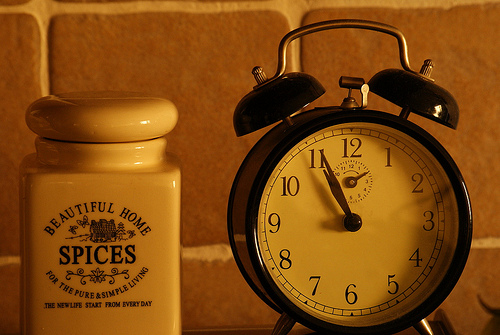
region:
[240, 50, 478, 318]
alarm clock kept in the table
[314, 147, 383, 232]
two needles in the clock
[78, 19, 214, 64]
brown color wall tiles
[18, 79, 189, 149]
top of the jar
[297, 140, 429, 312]
white color background of the clock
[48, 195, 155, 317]
text written in the jar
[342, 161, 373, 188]
alarm needle in the clcok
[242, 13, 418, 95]
handle of the clock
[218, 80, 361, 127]
black color alarm clock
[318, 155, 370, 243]
black color needles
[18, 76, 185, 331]
This is a jar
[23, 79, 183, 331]
The jar is made of glass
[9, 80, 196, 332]
The jar contains beautiful home spices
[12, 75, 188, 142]
The cap is round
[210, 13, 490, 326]
This is a clock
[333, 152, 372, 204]
There is a small clock within the big clock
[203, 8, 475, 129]
An alarm on the top of the clock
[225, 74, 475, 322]
The time is 10:55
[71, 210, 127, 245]
There is a small home on the jar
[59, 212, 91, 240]
Two butterflies flying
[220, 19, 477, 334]
clock sitting on table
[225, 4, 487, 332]
clock itself is round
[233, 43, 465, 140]
alarm bells on top of clock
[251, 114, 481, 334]
time shows 10:55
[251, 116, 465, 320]
regular numbers on clock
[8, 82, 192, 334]
container on the table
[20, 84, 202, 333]
container holds the spices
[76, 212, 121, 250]
picture of building on container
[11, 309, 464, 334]
table holding the items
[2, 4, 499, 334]
back wall is tile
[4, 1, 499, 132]
The wall is brick.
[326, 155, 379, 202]
Smaller clock on the clock.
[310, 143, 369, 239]
The clock hands are black.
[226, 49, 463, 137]
Bells on the clock.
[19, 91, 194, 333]
Spice jar next to the clock.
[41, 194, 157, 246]
Beautiful Home on the jar.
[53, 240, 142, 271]
Spices on the jar.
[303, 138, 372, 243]
The clock hands are both are "11".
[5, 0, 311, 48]
The grout is white.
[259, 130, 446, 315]
The numbers are black.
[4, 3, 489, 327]
a clock and some spices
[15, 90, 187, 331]
ceramic bottle of spices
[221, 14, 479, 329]
a vintage alarm clock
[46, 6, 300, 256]
ceramic square tile on wall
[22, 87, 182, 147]
lid of spice container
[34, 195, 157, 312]
lettering on spice container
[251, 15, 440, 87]
handle of alarm clock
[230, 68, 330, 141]
bell of alarm clock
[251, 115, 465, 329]
face of alarm clock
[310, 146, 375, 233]
hour, minute, second hands